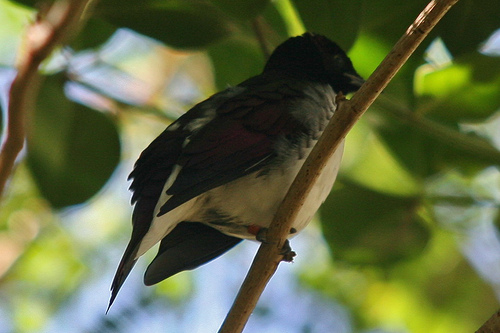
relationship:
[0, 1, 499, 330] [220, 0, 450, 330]
leaves on branch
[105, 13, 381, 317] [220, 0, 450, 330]
bird sitting on branch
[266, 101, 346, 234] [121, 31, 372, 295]
breast on bird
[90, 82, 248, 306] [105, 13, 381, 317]
wing on bird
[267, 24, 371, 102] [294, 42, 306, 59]
head covered in feathers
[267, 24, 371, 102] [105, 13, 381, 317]
head on bird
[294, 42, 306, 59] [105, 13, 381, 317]
feathers on bird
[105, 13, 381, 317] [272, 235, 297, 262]
bird has toes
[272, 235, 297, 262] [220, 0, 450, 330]
toes gripping branch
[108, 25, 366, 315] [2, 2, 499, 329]
bird in photo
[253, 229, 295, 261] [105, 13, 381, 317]
feet on bird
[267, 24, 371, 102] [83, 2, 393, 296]
head on bird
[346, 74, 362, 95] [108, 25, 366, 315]
beak on bird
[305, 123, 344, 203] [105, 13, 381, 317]
white chest on bird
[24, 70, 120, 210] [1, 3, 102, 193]
leaf on branch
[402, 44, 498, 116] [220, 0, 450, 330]
leaf in branch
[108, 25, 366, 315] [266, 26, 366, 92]
bird has head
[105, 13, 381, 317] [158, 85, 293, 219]
bird has wing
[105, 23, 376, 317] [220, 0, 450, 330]
bird perched on branch